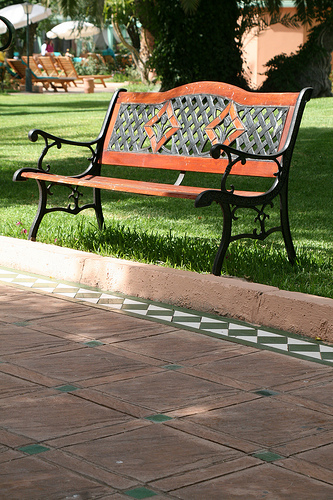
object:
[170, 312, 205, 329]
tile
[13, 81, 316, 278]
bench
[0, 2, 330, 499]
park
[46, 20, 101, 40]
umbrella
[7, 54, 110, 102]
seating area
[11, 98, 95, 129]
green space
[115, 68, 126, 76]
flowers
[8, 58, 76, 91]
chairs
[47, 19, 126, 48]
light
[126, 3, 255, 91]
tree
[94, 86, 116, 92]
concrete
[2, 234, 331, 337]
curb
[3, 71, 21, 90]
plant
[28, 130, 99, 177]
armrests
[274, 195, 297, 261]
legs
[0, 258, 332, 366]
border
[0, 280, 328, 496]
sidewalk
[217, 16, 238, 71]
ivy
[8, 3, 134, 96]
background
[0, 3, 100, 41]
two umbrellas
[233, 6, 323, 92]
building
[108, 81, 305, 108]
wood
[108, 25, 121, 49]
sun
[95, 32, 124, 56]
pool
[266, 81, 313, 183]
iron and wood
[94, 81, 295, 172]
back rest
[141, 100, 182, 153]
design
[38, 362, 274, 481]
stone squares